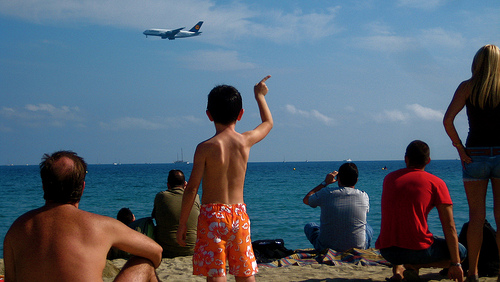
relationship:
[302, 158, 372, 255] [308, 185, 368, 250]
man in shirt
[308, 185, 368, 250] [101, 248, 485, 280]
shirt sitting in sand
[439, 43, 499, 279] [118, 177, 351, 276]
lady on a beach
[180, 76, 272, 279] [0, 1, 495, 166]
boy pointing to sky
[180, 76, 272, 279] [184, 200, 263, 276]
boy wearing swimsuit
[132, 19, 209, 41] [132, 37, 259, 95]
airplane in sky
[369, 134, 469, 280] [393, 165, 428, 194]
man in shirt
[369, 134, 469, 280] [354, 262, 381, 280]
man kneeling in sand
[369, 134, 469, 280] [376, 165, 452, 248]
man wearing red shirt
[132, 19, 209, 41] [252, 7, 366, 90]
airplane in sky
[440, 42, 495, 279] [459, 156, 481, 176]
woman in pocket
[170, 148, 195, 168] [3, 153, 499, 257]
boat on water